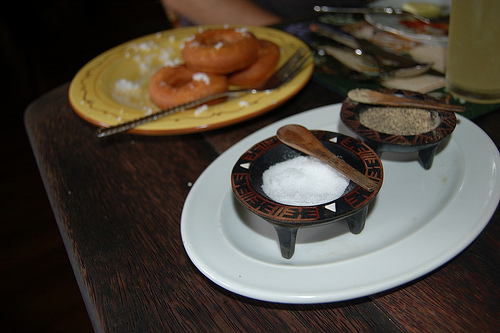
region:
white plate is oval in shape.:
[178, 90, 491, 298]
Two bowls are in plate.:
[229, 83, 454, 241]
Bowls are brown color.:
[244, 109, 445, 225]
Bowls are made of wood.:
[234, 98, 470, 255]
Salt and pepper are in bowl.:
[228, 88, 456, 242]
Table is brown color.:
[78, 162, 163, 309]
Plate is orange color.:
[53, 39, 289, 131]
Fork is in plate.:
[110, 52, 336, 133]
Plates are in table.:
[91, 70, 296, 240]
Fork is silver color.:
[94, 61, 324, 142]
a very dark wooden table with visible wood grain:
[25, 0, 497, 332]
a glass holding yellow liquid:
[443, 1, 499, 106]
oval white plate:
[180, 96, 499, 302]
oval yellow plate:
[68, 21, 312, 132]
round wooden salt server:
[231, 126, 382, 258]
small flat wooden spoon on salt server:
[232, 123, 382, 258]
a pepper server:
[340, 85, 457, 169]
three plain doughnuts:
[146, 26, 284, 110]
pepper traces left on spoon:
[346, 85, 381, 107]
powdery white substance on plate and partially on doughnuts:
[73, 20, 312, 131]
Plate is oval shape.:
[211, 83, 485, 303]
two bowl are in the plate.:
[238, 90, 441, 227]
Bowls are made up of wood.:
[241, 85, 438, 225]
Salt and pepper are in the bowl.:
[257, 102, 431, 221]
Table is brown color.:
[98, 206, 171, 325]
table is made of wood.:
[75, 149, 170, 293]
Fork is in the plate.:
[100, 41, 315, 159]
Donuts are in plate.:
[136, 29, 286, 118]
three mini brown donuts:
[153, 27, 285, 120]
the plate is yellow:
[80, 44, 151, 136]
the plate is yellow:
[154, 86, 209, 139]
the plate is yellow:
[95, 35, 220, 143]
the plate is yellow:
[87, 44, 285, 211]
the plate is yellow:
[122, 57, 249, 172]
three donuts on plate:
[98, 10, 310, 117]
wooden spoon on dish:
[293, 130, 364, 195]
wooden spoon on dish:
[333, 90, 453, 114]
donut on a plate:
[192, 25, 243, 63]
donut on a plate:
[154, 68, 214, 110]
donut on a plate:
[248, 45, 276, 80]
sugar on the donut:
[196, 74, 211, 84]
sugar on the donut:
[194, 102, 216, 116]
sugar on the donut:
[239, 100, 250, 109]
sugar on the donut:
[113, 74, 138, 94]